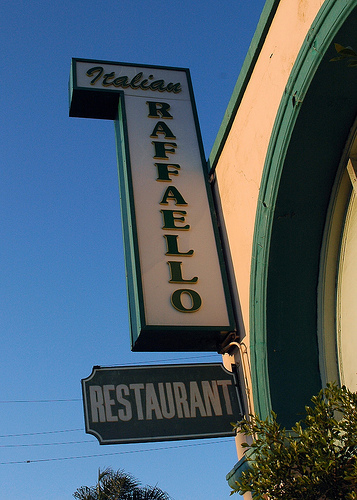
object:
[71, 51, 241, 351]
sign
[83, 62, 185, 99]
italian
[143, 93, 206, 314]
raffaello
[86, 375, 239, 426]
lettering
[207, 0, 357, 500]
building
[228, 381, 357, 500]
tree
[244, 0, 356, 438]
archway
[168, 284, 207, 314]
letter o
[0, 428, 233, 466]
power lines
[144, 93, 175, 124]
letter r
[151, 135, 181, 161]
letter f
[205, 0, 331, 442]
exterior wall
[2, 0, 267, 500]
sky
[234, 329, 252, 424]
pole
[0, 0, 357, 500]
background